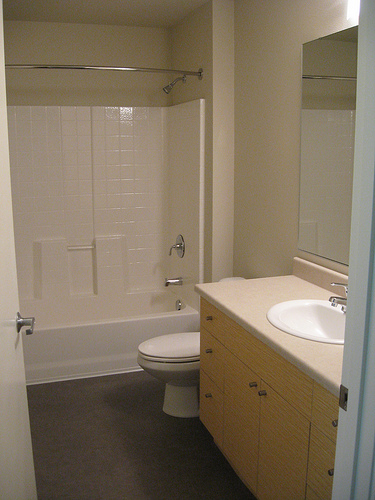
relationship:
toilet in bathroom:
[134, 328, 204, 418] [7, 7, 360, 489]